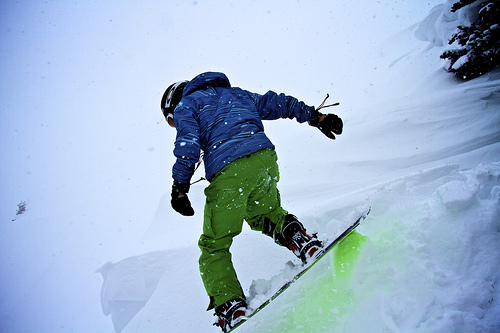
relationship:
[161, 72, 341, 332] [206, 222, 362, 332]
man on snowboard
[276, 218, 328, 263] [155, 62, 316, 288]
snow boot on man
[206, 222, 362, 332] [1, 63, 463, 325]
snowboard on snow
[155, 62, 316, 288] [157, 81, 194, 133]
man with helmet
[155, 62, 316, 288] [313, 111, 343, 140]
man wearing glove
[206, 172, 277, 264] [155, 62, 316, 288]
pants on man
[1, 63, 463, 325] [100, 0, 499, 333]
snow on slope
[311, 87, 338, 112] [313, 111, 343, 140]
strings on glove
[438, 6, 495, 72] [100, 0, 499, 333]
tree on slope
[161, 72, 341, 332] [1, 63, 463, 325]
man on snow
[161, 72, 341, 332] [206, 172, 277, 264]
man wears pants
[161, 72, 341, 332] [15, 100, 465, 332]
man on slope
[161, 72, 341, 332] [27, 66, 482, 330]
man going down hill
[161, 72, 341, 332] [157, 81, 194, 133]
man wears helmet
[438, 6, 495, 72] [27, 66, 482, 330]
tree on hill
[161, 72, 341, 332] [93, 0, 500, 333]
man on hill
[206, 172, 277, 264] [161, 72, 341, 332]
pants of man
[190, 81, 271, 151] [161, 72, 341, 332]
coat of man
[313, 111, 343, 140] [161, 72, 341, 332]
glove of man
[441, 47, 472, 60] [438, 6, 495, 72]
limbs of tree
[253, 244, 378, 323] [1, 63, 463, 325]
reflection on snow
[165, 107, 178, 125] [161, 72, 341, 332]
snow goggles of man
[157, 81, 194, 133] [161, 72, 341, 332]
helmet of man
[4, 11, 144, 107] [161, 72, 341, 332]
sky behind man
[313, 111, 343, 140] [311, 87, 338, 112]
glove with strings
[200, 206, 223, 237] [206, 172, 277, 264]
pocket on pants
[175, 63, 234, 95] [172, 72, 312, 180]
hood of coat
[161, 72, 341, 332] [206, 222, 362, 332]
man riding snowboard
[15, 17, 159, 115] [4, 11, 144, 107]
clouds in sky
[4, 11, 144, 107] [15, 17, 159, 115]
sky with clouds